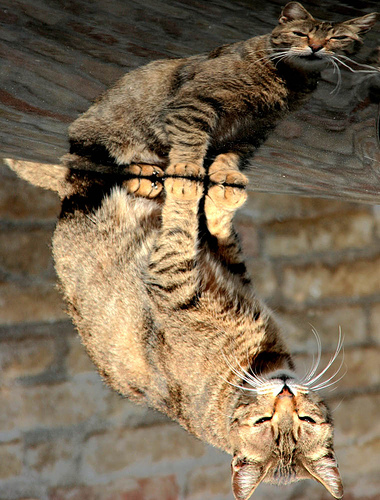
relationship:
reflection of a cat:
[93, 4, 374, 191] [71, 187, 341, 482]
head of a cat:
[270, 0, 379, 73] [63, 0, 378, 167]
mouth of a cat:
[261, 361, 299, 384] [2, 158, 355, 497]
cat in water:
[63, 0, 378, 167] [1, 158, 373, 498]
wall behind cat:
[64, 19, 130, 68] [68, 17, 360, 208]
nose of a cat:
[267, 382, 296, 411] [65, 180, 354, 498]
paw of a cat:
[162, 174, 203, 201] [2, 158, 355, 497]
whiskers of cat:
[212, 322, 352, 393] [112, 270, 358, 469]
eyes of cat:
[287, 24, 351, 42] [66, 1, 378, 186]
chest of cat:
[221, 53, 304, 113] [59, 2, 377, 308]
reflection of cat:
[59, 2, 378, 183] [100, 51, 314, 169]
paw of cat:
[161, 172, 207, 208] [2, 158, 355, 497]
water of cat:
[1, 158, 373, 498] [66, 1, 378, 186]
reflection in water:
[3, 158, 377, 499] [1, 158, 373, 498]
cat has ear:
[2, 158, 355, 497] [231, 453, 272, 499]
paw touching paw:
[166, 158, 201, 180] [207, 162, 248, 186]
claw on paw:
[194, 167, 198, 178] [121, 154, 259, 182]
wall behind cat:
[5, 178, 379, 499] [2, 158, 355, 497]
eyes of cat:
[289, 29, 345, 45] [66, 1, 378, 186]